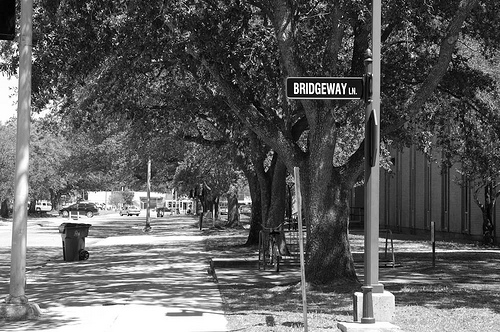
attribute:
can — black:
[59, 221, 90, 261]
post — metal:
[364, 0, 384, 294]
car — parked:
[119, 204, 140, 217]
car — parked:
[59, 202, 101, 217]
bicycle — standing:
[259, 222, 285, 274]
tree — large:
[2, 2, 499, 293]